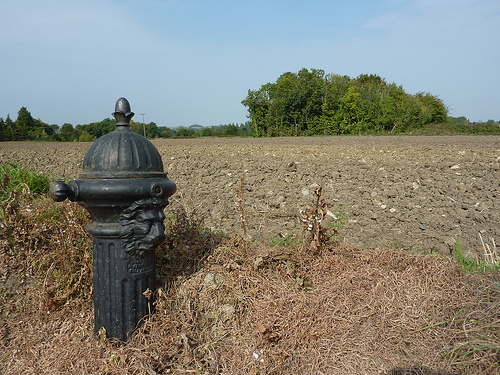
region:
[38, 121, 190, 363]
black hydrant on hill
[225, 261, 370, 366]
brown grass on slope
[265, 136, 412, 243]
dirt is light brown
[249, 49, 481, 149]
green trees in distance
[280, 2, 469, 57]
blue and clear sky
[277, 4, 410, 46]
few clouds in sky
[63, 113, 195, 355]
grey hydrant on hill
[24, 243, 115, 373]
brown and dead grass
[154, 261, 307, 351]
brown grass near hydrant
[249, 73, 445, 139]
green and tall trees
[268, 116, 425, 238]
dry field by hydrant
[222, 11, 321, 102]
blue and clear sky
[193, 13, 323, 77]
no clouds in sky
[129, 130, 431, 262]
no crops have grown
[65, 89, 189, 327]
black fire hydrant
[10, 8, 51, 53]
white clouds in blue sky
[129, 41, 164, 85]
white clouds in blue sky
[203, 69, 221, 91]
white clouds in blue sky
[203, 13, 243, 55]
white clouds in blue sky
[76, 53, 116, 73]
white clouds in blue sky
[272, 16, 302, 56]
white clouds in blue sky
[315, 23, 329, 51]
white clouds in blue sky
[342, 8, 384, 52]
white clouds in blue sky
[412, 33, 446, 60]
white clouds in blue sky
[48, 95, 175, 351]
a small black fire hydrant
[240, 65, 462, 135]
a tiny patch of forest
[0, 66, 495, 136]
trees surrounding a field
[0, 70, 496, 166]
a forest surrounding a farm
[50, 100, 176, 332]
cast iron fire hydrant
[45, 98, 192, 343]
a dark metal pillar on a hill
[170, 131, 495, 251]
dying dried out field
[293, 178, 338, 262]
a tiny weed on a hill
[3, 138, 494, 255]
dehydrated empty farm space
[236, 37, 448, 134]
forest under a blue sky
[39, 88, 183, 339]
green hydrant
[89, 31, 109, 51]
white clouds in blue sky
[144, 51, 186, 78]
white clouds in blue sky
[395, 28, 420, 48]
white clouds in blue sky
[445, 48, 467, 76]
white clouds in blue sky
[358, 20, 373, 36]
white clouds in blue sky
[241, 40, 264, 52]
white clouds in blue sky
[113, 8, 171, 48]
white clouds in blue sky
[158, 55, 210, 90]
white clouds in blue sky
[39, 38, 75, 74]
white clouds in blue sky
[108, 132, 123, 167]
black raised line on post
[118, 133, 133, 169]
black raised line on post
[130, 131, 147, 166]
black raised line on post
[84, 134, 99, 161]
black raised line on post